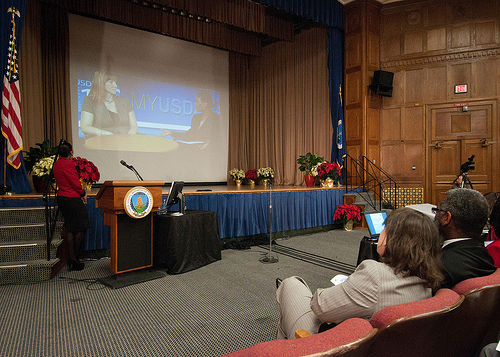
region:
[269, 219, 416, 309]
the woman is sitted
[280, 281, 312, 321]
the pants are brown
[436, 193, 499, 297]
the man has glasses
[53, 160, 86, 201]
the top is red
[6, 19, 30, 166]
the flagg is american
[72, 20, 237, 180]
the screen is on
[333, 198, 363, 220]
roses are in the pot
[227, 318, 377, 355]
the chair is empty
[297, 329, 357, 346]
the cushion is orange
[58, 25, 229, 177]
screen with image on it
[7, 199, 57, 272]
stairs near the stage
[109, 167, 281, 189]
stage in the front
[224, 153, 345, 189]
plants on the stage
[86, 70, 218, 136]
people on the screen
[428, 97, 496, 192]
doors to the room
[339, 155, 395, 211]
stairs by the stage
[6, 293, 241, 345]
carpet on the floor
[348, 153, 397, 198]
rails on the stairs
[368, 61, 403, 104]
speaker in the room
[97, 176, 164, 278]
a wooden podium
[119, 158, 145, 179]
a microphone on a podium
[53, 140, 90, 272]
a woman standing next to a podium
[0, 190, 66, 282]
stairs going up to a stage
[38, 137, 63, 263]
a black hand rail on stairs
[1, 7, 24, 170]
an American flag on a stage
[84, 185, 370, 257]
a blue skirt on the front of a stage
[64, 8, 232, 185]
a large video screen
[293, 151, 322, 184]
a potted plant on a stage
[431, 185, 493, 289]
a man in a black suit coat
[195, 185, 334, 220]
blue cloth on table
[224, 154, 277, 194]
red and white flowers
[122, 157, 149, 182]
speaker attached to lectern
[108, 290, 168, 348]
carpet is dark grey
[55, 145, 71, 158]
woman has brown hair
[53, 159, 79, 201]
woman has red shirt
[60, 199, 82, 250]
woman has black pants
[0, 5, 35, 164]
US flag on pole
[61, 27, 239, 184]
large white projection screen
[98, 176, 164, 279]
a brown wood podium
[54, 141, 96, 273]
a woman standing next to a podium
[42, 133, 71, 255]
black railing on stairs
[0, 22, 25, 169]
an American flag on a stage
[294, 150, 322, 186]
a green potted plant on a stage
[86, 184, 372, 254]
a blue skirt across the front of a stage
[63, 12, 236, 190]
a large video screen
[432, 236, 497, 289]
a man in a black suitcoat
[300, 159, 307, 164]
A green leaf on a plant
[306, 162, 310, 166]
A green leaf on a plant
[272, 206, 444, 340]
woman wearing beige suit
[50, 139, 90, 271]
woman wearing tall black boots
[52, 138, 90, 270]
woman wearing red shirt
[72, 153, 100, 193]
red flowers in gold vase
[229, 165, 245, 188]
white flowers in gold pot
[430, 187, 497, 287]
man wearing black glasses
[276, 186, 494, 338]
woman and man sitting next to each other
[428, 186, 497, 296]
man wearing black suit jacket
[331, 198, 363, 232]
red flowers in gold vase on floor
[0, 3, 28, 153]
the flag of the united states of america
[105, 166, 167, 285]
decorated brown podium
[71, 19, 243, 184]
large faded screen on stage